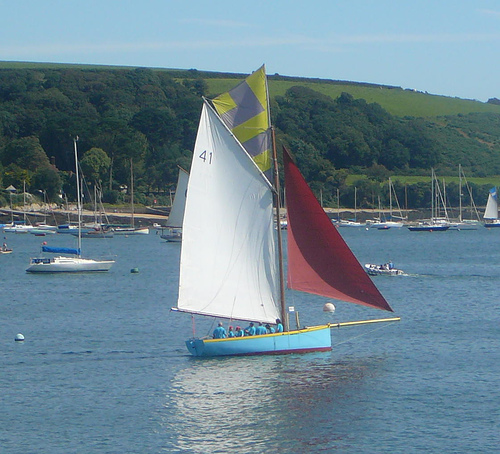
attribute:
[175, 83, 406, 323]
sail — red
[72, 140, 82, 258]
pole — white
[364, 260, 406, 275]
motorboat — small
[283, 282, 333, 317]
buoy — small, white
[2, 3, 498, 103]
sky — blue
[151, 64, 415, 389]
sail — yellow, grey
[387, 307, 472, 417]
water — calm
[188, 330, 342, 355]
boat — blue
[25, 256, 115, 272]
white boat — white 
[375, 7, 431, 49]
sky — blue 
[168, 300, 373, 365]
boat — blue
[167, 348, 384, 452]
reflection — blue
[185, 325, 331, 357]
small boat — small 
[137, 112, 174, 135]
leaves — on the trees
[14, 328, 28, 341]
bobber — white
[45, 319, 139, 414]
water — calm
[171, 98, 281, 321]
mast — tall, white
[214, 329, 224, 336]
shirt — blue